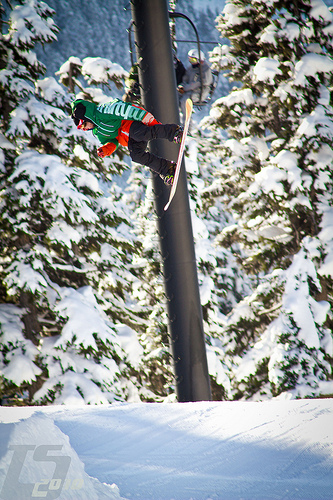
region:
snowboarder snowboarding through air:
[70, 96, 194, 211]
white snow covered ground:
[0, 397, 331, 498]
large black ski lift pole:
[122, 0, 212, 401]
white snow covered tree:
[211, 240, 329, 398]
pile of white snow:
[0, 409, 125, 497]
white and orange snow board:
[159, 96, 191, 210]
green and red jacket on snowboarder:
[69, 96, 159, 156]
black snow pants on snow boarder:
[126, 118, 174, 178]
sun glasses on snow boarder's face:
[80, 120, 87, 130]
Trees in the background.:
[190, 4, 225, 23]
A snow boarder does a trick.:
[65, 95, 192, 206]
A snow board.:
[161, 94, 187, 206]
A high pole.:
[154, 218, 209, 393]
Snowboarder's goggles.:
[73, 117, 84, 128]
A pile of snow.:
[2, 410, 125, 495]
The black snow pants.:
[128, 152, 171, 170]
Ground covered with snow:
[0, 398, 331, 498]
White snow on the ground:
[0, 402, 330, 499]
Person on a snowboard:
[71, 97, 210, 209]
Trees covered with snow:
[0, 0, 332, 406]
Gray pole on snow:
[127, 0, 214, 401]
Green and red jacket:
[74, 97, 153, 156]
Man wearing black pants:
[128, 120, 180, 180]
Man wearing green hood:
[72, 96, 94, 131]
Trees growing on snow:
[0, 0, 332, 405]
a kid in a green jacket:
[73, 97, 197, 205]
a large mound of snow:
[0, 402, 124, 499]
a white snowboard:
[162, 101, 194, 212]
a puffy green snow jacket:
[72, 96, 150, 159]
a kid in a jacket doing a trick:
[67, 91, 196, 210]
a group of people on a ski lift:
[119, 15, 226, 102]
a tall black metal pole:
[115, 0, 213, 404]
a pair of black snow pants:
[131, 123, 184, 183]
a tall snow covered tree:
[1, 13, 137, 400]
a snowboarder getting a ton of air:
[64, 87, 201, 206]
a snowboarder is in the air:
[53, 82, 204, 216]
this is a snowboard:
[169, 90, 209, 215]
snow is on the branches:
[1, 169, 147, 325]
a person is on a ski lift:
[172, 34, 215, 108]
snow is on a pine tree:
[1, 366, 152, 401]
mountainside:
[54, 2, 127, 56]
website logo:
[1, 472, 88, 499]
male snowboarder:
[51, 92, 176, 183]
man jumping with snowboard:
[65, 91, 174, 180]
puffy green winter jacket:
[70, 96, 153, 160]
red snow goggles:
[73, 116, 89, 132]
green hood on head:
[69, 91, 98, 122]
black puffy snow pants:
[127, 117, 185, 172]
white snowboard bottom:
[160, 98, 199, 221]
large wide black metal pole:
[127, 4, 216, 399]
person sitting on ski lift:
[177, 35, 212, 126]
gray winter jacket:
[179, 59, 209, 103]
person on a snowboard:
[59, 85, 194, 214]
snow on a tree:
[76, 53, 128, 91]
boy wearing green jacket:
[65, 96, 185, 186]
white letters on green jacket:
[97, 97, 144, 121]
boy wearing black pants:
[61, 94, 186, 190]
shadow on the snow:
[49, 411, 328, 497]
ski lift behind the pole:
[124, 10, 204, 114]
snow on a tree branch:
[53, 284, 110, 342]